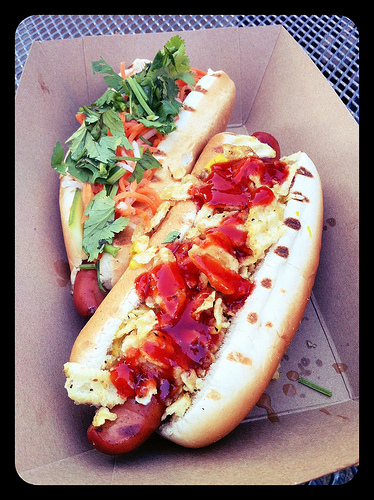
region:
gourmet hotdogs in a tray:
[57, 40, 336, 457]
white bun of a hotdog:
[66, 290, 119, 359]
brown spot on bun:
[244, 310, 259, 329]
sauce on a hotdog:
[150, 260, 186, 327]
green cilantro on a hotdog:
[104, 59, 182, 108]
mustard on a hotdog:
[204, 149, 226, 175]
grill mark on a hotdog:
[115, 417, 149, 441]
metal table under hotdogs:
[309, 16, 358, 96]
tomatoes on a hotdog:
[113, 180, 162, 223]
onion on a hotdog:
[128, 136, 142, 158]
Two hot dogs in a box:
[46, 22, 345, 496]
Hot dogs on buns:
[77, 104, 276, 433]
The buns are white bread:
[54, 52, 274, 424]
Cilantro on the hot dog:
[65, 37, 180, 272]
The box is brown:
[19, 64, 355, 466]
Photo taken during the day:
[1, 3, 348, 475]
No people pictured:
[19, 18, 355, 494]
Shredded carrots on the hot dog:
[84, 77, 196, 242]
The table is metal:
[6, 13, 363, 128]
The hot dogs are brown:
[36, 258, 140, 466]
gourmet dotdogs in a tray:
[47, 30, 330, 469]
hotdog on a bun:
[87, 403, 163, 450]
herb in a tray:
[294, 373, 334, 400]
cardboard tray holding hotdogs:
[233, 432, 358, 484]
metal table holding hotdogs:
[306, 13, 360, 100]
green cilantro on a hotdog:
[71, 123, 120, 187]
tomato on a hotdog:
[119, 182, 159, 207]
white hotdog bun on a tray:
[253, 264, 300, 376]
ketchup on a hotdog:
[143, 339, 180, 368]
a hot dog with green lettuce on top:
[51, 42, 220, 315]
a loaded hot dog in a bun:
[83, 120, 319, 458]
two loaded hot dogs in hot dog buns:
[53, 43, 314, 454]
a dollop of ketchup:
[190, 155, 295, 213]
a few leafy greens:
[88, 32, 196, 120]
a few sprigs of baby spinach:
[49, 103, 140, 183]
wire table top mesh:
[305, 17, 362, 95]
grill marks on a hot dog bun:
[259, 160, 320, 299]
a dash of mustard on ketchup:
[202, 152, 228, 169]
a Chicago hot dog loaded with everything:
[60, 129, 324, 459]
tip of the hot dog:
[64, 401, 152, 481]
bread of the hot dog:
[213, 307, 300, 424]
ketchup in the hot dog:
[124, 165, 289, 388]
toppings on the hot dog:
[98, 162, 295, 390]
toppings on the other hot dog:
[79, 61, 203, 202]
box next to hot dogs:
[13, 250, 54, 317]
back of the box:
[60, 23, 326, 73]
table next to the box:
[319, 26, 354, 61]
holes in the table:
[19, 16, 76, 43]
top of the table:
[320, 32, 354, 67]